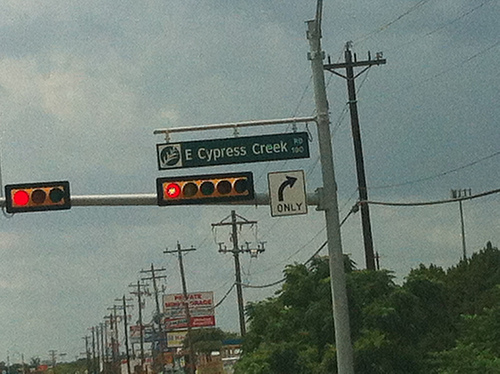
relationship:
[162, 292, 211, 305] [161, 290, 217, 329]
lettering printed on billboard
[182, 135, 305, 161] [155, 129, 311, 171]
lettering printed on street sign